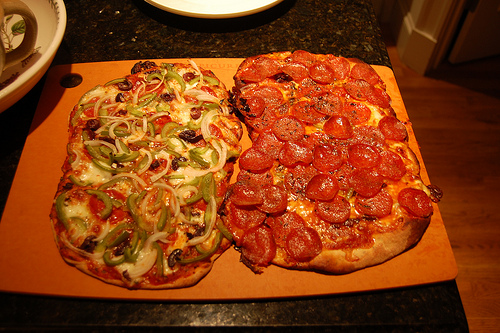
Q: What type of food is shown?
A: Pizza.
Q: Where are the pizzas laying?
A: Cutting board.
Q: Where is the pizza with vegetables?
A: Left.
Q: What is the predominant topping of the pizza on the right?
A: Pepperoni.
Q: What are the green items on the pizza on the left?
A: Peppers.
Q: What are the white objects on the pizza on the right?
A: Onions.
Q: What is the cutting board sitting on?
A: Counter top.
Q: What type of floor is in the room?
A: Hardwood.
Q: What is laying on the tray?
A: Pizza.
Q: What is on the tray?
A: Pizza.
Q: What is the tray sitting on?
A: Countertop.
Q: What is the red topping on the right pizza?
A: Pepperoni.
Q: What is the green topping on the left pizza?
A: Peppers.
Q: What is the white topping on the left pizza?
A: Onions.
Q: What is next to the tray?
A: Bowl.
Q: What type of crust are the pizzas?
A: Thin crust.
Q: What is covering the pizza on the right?
A: Pepperoni.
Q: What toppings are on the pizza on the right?
A: Onions, peppers, olives.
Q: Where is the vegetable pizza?
A: On the left.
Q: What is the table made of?
A: Wood.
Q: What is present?
A: Food.